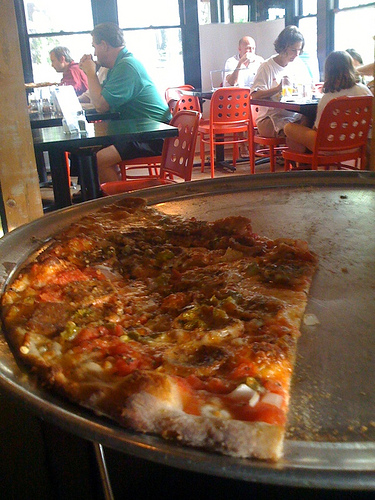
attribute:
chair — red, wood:
[207, 84, 261, 189]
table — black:
[29, 104, 183, 198]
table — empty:
[23, 76, 213, 187]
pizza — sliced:
[0, 166, 372, 498]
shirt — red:
[62, 64, 89, 91]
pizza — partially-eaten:
[1, 195, 321, 462]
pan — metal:
[1, 168, 373, 489]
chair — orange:
[97, 108, 205, 198]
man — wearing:
[48, 43, 91, 97]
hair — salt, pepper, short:
[47, 44, 73, 64]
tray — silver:
[0, 165, 373, 490]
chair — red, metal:
[208, 88, 246, 135]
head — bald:
[233, 32, 258, 65]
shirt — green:
[98, 47, 174, 128]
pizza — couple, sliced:
[37, 185, 341, 465]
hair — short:
[273, 25, 300, 46]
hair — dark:
[323, 48, 354, 87]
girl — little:
[260, 20, 330, 115]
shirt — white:
[258, 55, 337, 103]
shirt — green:
[93, 55, 156, 115]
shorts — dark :
[111, 138, 159, 153]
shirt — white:
[221, 56, 268, 94]